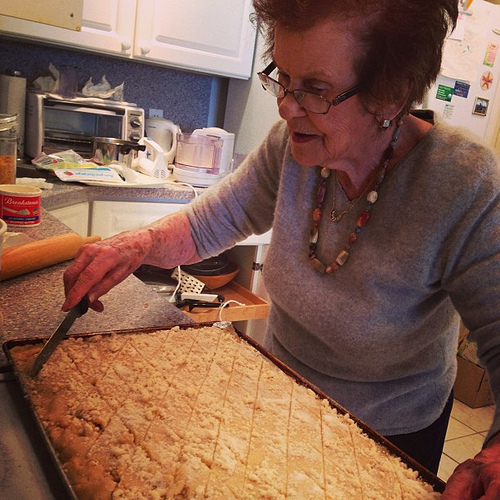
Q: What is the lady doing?
A: Cooking.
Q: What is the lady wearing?
A: Clothes.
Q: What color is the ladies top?
A: Grey.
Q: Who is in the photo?
A: A lady.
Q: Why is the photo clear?
A: Its during the day.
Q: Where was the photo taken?
A: In a kitchen.